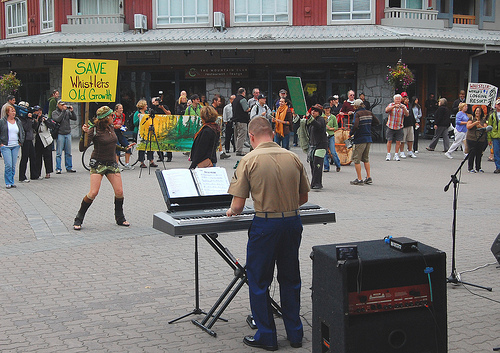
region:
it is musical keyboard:
[152, 165, 342, 235]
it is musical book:
[156, 163, 231, 199]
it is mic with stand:
[426, 116, 494, 291]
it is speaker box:
[315, 231, 451, 349]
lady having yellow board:
[60, 56, 127, 232]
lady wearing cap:
[95, 103, 115, 119]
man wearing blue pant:
[250, 211, 305, 351]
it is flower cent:
[382, 61, 417, 88]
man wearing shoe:
[346, 168, 372, 185]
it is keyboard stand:
[193, 233, 301, 343]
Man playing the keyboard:
[246, 120, 311, 350]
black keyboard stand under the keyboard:
[191, 229, 284, 341]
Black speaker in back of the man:
[311, 233, 448, 350]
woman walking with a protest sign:
[59, 55, 131, 228]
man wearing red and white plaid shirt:
[386, 100, 405, 128]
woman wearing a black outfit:
[466, 106, 490, 176]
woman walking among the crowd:
[443, 102, 478, 160]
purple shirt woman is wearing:
[454, 109, 469, 128]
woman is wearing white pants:
[447, 126, 469, 154]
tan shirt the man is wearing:
[226, 139, 308, 211]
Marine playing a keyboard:
[213, 110, 307, 347]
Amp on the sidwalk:
[305, 230, 468, 350]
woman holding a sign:
[61, 53, 121, 123]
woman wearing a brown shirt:
[83, 125, 125, 165]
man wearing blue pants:
[234, 202, 319, 340]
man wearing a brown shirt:
[222, 140, 314, 221]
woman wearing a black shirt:
[307, 115, 327, 149]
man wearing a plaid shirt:
[386, 104, 410, 131]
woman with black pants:
[465, 135, 497, 177]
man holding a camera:
[51, 96, 83, 123]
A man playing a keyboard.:
[152, 113, 337, 351]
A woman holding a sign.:
[60, 56, 134, 229]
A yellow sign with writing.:
[61, 59, 116, 103]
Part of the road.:
[379, 204, 399, 216]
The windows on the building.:
[156, 2, 212, 25]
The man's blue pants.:
[248, 216, 303, 348]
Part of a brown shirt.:
[268, 168, 288, 191]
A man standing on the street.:
[383, 93, 409, 163]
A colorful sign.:
[137, 118, 221, 150]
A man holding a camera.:
[52, 99, 77, 175]